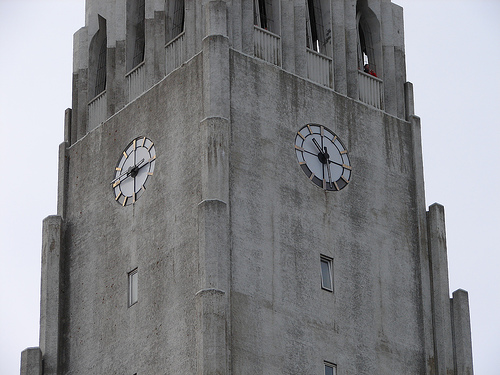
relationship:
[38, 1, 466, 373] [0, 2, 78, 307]
tower against sky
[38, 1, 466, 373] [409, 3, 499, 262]
tower against sky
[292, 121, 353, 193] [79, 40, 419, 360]
clock on tower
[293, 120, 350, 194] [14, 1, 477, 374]
clock face on tower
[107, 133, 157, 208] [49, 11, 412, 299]
clock face on building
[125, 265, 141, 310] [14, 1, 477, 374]
window on tower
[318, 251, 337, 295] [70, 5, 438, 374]
window on building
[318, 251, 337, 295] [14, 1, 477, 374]
window on tower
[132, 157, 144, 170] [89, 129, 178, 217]
hand on clock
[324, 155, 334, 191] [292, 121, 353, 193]
hand on clock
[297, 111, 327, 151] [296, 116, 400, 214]
number on clock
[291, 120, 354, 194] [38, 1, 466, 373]
clock face on tower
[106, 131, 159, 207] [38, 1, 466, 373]
clock face on tower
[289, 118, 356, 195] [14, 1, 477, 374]
clock on tower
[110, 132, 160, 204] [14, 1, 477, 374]
clock on tower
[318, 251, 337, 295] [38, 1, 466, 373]
window on tower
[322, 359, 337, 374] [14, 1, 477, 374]
small window on tower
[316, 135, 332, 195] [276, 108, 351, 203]
hand on clock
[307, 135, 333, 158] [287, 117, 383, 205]
hand on clock face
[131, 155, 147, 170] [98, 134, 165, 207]
hand on clock face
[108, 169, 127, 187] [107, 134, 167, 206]
hand on clock face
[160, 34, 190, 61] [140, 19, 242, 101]
railing on balcony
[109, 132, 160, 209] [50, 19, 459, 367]
clock on tower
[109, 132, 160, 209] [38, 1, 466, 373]
clock on tower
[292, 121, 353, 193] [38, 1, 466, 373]
clock on tower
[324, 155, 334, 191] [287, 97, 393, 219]
hand on clock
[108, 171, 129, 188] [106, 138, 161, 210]
hand on clock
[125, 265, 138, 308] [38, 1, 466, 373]
window on tower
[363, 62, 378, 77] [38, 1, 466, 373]
person on tower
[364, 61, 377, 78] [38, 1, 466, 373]
red object on tower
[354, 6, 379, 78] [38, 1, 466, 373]
window on top of tower